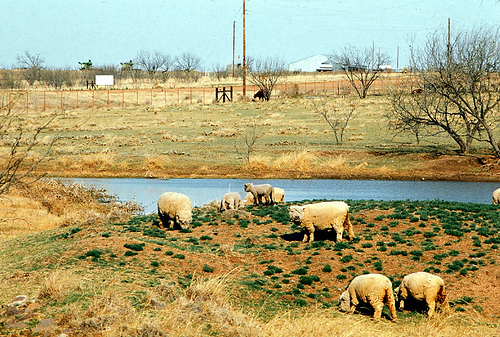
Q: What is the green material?
A: Grass.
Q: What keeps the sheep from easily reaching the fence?
A: Water.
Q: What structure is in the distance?
A: Barn.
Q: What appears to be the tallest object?
A: Utility pole.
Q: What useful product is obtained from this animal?
A: Wool.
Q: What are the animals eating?
A: Grass.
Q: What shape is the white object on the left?
A: Rectangle.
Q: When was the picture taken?
A: Daytime.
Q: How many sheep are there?
A: Seven.